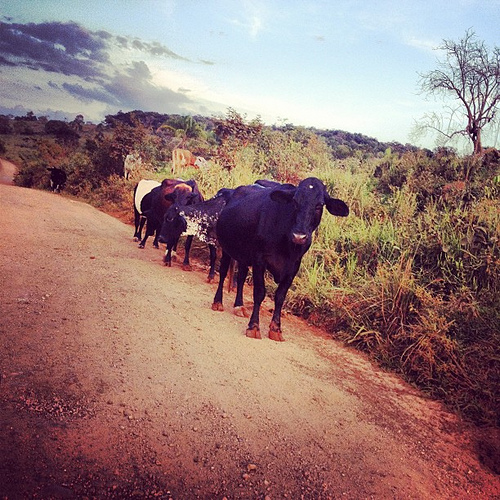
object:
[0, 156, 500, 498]
dirt road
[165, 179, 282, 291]
cow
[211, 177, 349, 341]
cow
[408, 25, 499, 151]
tree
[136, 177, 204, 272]
cow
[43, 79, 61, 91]
cloud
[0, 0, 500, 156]
sky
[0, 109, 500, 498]
country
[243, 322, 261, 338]
hoof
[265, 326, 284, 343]
hoof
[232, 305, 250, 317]
hoof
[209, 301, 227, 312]
hoof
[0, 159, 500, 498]
country road